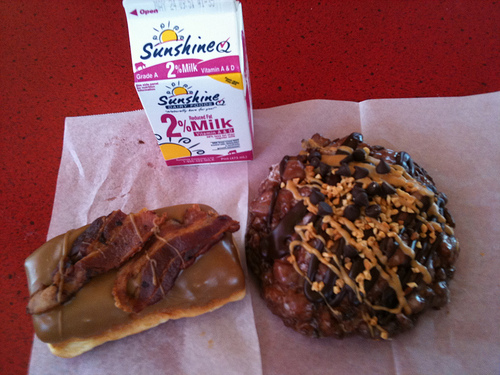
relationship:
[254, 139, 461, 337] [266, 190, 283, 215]
donut has chocolate frosting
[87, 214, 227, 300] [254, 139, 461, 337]
bacon on donut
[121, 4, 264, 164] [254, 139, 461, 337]
milk next to donuts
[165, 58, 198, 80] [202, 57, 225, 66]
2% milk in purple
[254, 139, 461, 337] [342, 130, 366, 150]
donut has chocolate chips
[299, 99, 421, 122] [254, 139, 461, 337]
paper has donuts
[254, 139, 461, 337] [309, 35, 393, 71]
donuts on table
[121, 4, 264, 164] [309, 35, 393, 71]
milk on table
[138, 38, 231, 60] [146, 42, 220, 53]
sunshine written in blue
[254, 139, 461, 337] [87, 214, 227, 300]
donut has two strips of bacon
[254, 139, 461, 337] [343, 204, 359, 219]
donut has multiple topping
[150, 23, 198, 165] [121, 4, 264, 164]
suns on carton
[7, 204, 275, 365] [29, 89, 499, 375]
food on paper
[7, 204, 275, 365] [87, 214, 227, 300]
pastry has bacon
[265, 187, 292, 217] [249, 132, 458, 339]
chocolate drizzled on donut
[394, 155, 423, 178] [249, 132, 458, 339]
icing on donut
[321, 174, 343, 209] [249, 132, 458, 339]
nuts on top of donut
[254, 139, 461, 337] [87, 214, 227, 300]
donut has bacon